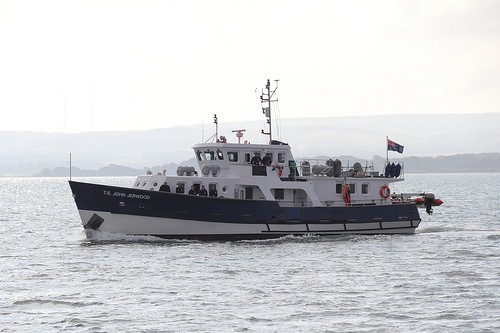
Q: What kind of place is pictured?
A: It is an ocean.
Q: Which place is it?
A: It is an ocean.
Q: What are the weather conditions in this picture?
A: It is clear.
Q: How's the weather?
A: It is clear.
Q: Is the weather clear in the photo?
A: Yes, it is clear.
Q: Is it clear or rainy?
A: It is clear.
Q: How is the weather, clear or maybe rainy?
A: It is clear.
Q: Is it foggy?
A: No, it is clear.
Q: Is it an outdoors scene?
A: Yes, it is outdoors.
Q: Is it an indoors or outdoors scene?
A: It is outdoors.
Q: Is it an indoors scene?
A: No, it is outdoors.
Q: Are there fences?
A: No, there are no fences.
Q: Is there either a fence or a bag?
A: No, there are no fences or bags.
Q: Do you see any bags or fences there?
A: No, there are no fences or bags.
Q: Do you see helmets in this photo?
A: No, there are no helmets.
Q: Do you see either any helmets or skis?
A: No, there are no helmets or skis.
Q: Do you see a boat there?
A: Yes, there is a boat.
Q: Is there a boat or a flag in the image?
A: Yes, there is a boat.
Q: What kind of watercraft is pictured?
A: The watercraft is a boat.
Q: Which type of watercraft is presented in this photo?
A: The watercraft is a boat.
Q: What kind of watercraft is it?
A: The watercraft is a boat.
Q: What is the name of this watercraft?
A: This is a boat.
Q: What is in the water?
A: The boat is in the water.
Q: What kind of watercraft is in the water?
A: The watercraft is a boat.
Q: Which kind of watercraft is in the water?
A: The watercraft is a boat.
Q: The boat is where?
A: The boat is in the water.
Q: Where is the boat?
A: The boat is in the water.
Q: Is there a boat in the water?
A: Yes, there is a boat in the water.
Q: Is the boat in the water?
A: Yes, the boat is in the water.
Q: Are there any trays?
A: No, there are no trays.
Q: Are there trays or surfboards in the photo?
A: No, there are no trays or surfboards.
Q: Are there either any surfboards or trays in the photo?
A: No, there are no trays or surfboards.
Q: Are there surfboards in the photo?
A: No, there are no surfboards.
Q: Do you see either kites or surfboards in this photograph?
A: No, there are no surfboards or kites.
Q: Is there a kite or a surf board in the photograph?
A: No, there are no surfboards or kites.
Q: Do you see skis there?
A: No, there are no skis.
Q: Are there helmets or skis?
A: No, there are no skis or helmets.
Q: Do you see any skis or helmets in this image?
A: No, there are no skis or helmets.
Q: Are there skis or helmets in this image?
A: No, there are no skis or helmets.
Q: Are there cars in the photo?
A: No, there are no cars.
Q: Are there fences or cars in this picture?
A: No, there are no cars or fences.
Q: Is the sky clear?
A: Yes, the sky is clear.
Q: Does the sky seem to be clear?
A: Yes, the sky is clear.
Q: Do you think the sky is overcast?
A: No, the sky is clear.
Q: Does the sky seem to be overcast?
A: No, the sky is clear.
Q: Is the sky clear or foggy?
A: The sky is clear.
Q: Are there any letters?
A: Yes, there are letters.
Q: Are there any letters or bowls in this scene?
A: Yes, there are letters.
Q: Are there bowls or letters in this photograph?
A: Yes, there are letters.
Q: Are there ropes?
A: No, there are no ropes.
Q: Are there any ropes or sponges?
A: No, there are no ropes or sponges.